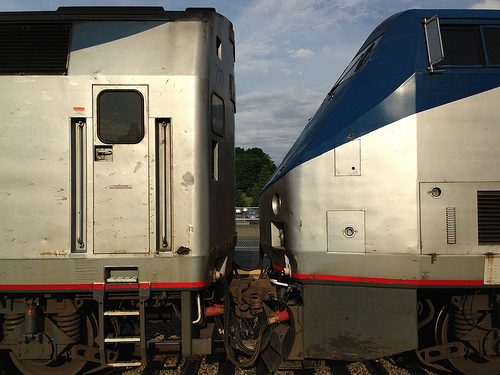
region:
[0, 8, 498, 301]
gray and blue train cabins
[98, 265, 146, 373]
steps of a stairway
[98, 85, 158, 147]
small black window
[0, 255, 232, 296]
red line in the cabin in the left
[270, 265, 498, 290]
red line in the cabin in the right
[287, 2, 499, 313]
gray and blue cabin in the right side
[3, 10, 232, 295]
gray cabin in the left side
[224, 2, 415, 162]
blue and cloudy sky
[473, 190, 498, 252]
little window in the corner of cabin in the right side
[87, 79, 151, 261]
small gray door in cabin train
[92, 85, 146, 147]
A tinted window in a door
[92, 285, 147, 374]
A silver stepladder to train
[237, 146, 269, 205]
A large green tree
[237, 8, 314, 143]
The sky is mostly cloudy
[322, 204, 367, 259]
An access panel on traincar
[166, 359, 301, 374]
Railroad tracks under a train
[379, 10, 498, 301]
The train car is red, blue, and silver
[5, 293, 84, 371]
The under-carriage is rusty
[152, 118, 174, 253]
A handgrip to assist in climbing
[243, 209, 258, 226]
Grey car parked in the back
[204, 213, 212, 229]
edge of a cabin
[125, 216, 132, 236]
part of a stair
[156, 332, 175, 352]
part of a steel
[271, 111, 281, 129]
part of the sky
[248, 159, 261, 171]
tip of a train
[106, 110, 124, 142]
part of a window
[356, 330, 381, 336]
bottom of a plane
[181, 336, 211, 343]
edge of a train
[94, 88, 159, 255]
a door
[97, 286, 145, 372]
stairs below the train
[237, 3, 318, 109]
white clouds in the sky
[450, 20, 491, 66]
a window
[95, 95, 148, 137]
a window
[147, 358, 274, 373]
a train track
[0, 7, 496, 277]
a train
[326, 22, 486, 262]
the train is blue and grey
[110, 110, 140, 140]
a reflection in the window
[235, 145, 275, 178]
a green bush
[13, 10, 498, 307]
the train on the tracks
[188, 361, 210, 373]
gravel on the tracks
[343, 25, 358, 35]
the clear blue sky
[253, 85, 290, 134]
clouds in the sky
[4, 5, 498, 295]
the train is blue silver and red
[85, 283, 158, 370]
the steps to the train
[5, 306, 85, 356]
the suspension of the train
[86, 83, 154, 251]
the door is closed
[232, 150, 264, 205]
the trees with green leaves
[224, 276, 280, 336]
the two cars connected